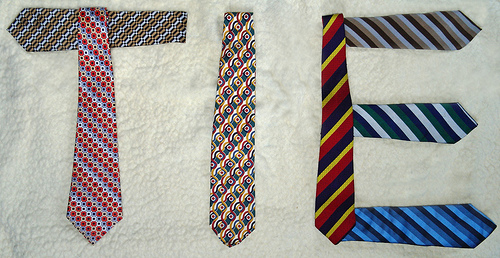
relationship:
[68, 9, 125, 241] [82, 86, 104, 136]
tie has dots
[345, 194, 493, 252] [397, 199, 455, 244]
tie has stripes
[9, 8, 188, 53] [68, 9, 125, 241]
tie underneath tie